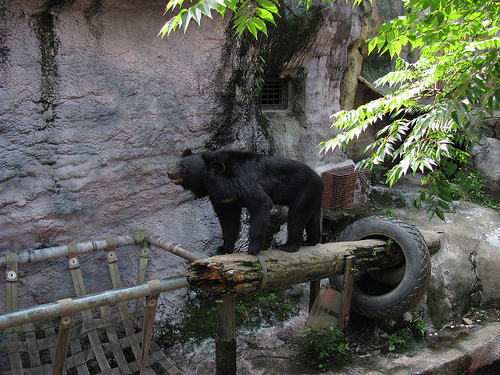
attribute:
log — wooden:
[184, 226, 441, 305]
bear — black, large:
[164, 145, 326, 255]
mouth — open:
[168, 173, 186, 184]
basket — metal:
[320, 162, 371, 222]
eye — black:
[181, 164, 187, 169]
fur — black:
[171, 144, 325, 254]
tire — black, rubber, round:
[328, 215, 432, 325]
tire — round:
[326, 212, 434, 320]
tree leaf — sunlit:
[382, 145, 395, 158]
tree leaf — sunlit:
[353, 125, 362, 139]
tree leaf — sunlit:
[348, 128, 355, 142]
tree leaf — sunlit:
[366, 100, 375, 115]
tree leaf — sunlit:
[323, 140, 332, 153]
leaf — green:
[410, 158, 420, 178]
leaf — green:
[394, 128, 409, 138]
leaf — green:
[377, 111, 384, 121]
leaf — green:
[367, 116, 374, 126]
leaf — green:
[362, 143, 372, 153]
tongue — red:
[167, 171, 181, 184]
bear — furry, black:
[174, 146, 320, 253]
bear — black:
[170, 150, 330, 253]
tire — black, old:
[342, 212, 429, 314]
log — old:
[184, 231, 394, 303]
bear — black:
[162, 146, 332, 245]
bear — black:
[173, 140, 326, 251]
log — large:
[193, 231, 389, 299]